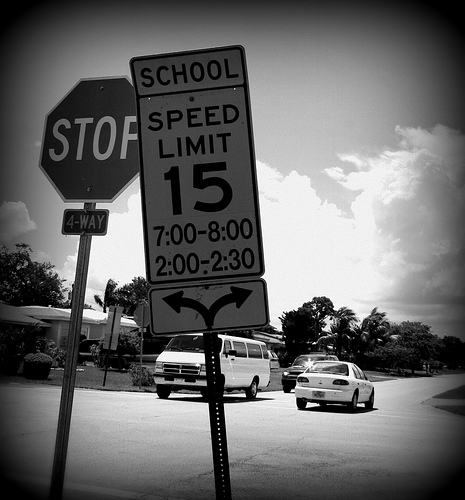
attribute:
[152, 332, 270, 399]
van — large, white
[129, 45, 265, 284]
sign — school zone, speed limit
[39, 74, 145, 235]
stop sign — 4-way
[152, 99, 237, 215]
limit — speed, black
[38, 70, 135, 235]
sign — is stop, is 4-way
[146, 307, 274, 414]
van — white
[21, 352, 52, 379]
bush — small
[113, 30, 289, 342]
sign — black, white, speed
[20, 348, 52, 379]
bush — lovely, manicured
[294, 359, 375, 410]
car — white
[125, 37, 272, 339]
sign — speed limit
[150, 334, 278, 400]
van — white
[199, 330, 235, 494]
pole — metal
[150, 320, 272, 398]
van — white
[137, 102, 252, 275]
letters — black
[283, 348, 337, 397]
car — black